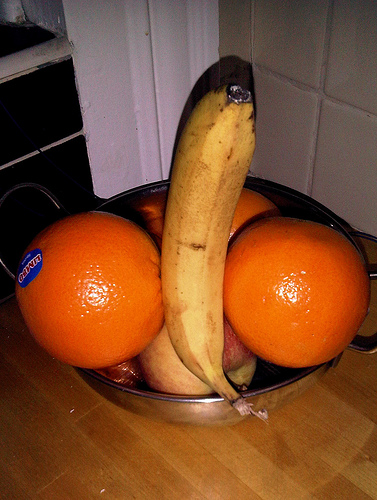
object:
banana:
[160, 82, 255, 416]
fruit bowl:
[56, 175, 377, 426]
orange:
[15, 209, 163, 371]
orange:
[223, 217, 370, 369]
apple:
[141, 301, 256, 400]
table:
[0, 225, 377, 498]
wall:
[220, 0, 377, 240]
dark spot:
[187, 243, 206, 253]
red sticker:
[15, 247, 42, 287]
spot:
[69, 408, 74, 414]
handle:
[349, 269, 377, 354]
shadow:
[178, 56, 257, 165]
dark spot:
[227, 84, 251, 105]